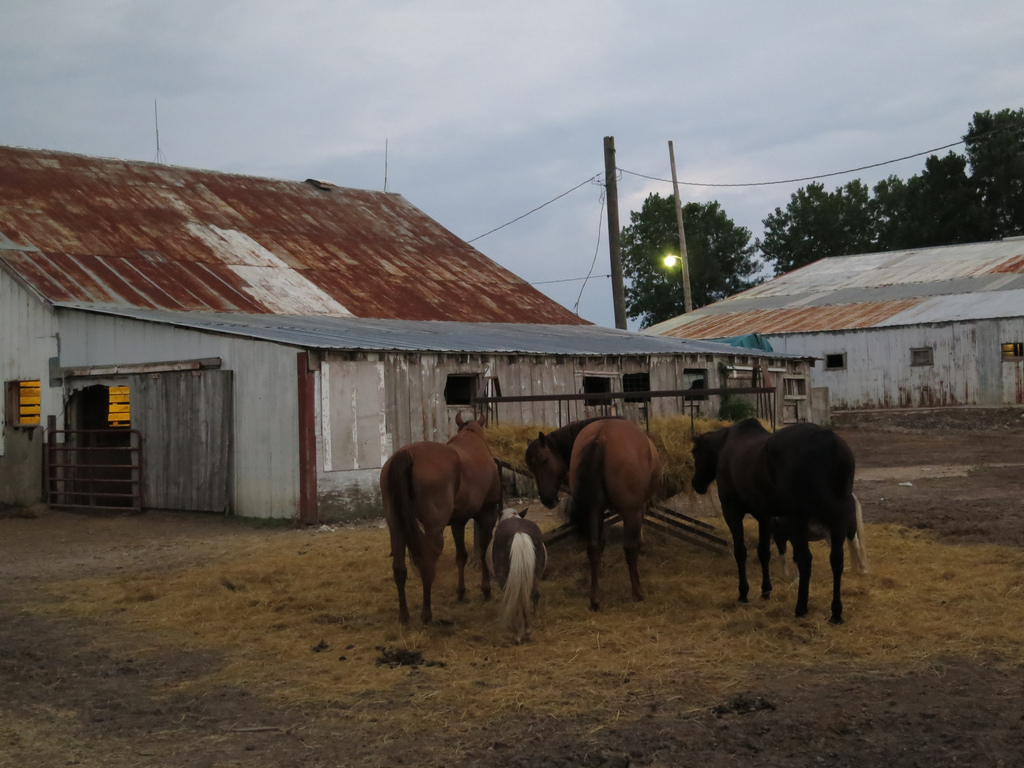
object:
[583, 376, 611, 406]
window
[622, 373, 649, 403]
window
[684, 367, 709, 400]
window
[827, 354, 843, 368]
window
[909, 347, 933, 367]
window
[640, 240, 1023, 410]
building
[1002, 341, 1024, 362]
window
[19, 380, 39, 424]
window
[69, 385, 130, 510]
window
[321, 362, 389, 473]
window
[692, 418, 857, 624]
horse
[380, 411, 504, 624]
horse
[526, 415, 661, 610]
horse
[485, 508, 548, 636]
pony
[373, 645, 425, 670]
manure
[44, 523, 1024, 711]
hay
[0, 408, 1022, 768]
ground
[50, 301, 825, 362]
roof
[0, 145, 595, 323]
roof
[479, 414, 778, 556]
hay trough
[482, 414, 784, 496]
hay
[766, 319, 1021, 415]
building side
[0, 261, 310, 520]
building side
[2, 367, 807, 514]
window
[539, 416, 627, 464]
mane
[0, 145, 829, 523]
building